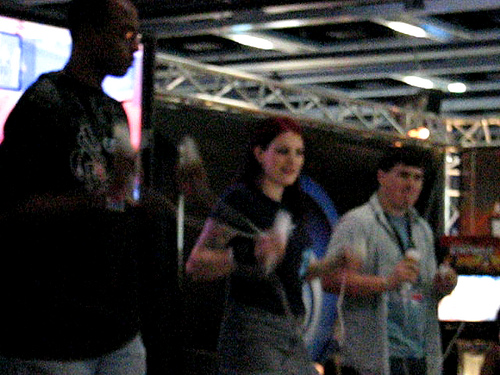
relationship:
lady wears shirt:
[186, 116, 358, 375] [205, 181, 314, 318]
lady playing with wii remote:
[186, 116, 358, 375] [261, 205, 292, 276]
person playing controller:
[324, 145, 458, 375] [397, 245, 425, 297]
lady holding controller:
[186, 116, 358, 375] [254, 206, 299, 278]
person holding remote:
[319, 142, 462, 373] [406, 247, 421, 266]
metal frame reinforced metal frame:
[151, 0, 498, 151] [151, 0, 498, 151]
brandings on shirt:
[69, 99, 147, 222] [10, 71, 147, 367]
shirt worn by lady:
[205, 181, 314, 318] [186, 116, 358, 375]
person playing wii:
[0, 0, 151, 374] [94, 114, 151, 208]